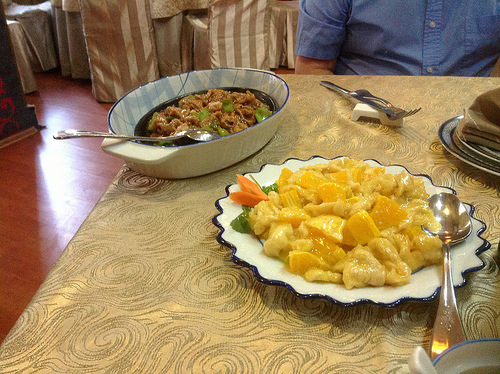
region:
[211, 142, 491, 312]
a white dish on a table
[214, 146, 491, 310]
dish with food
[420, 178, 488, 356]
a silver spoon on side a dish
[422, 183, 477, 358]
a tablespoon on a dish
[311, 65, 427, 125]
a fork on a table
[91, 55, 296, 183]
a white bowl on a table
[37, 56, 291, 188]
a spoon in a bowl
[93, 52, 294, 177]
meat in a bowl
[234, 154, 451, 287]
a salad of potato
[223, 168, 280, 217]
a slice of carrot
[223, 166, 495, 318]
the pasta on the plate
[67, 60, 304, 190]
the dish on the table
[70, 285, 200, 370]
the table cloth with swirl pattern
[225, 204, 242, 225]
garnish on the pasta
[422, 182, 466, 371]
the metal spoon in the pasta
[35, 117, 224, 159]
the giant spoon in the dish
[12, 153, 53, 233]
the floor is hardwood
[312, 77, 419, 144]
the knife and fork on the table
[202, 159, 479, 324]
the plate has ridged edge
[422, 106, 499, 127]
the stack of napkins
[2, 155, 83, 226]
a dark teak wood floor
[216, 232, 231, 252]
dark blue trim on plate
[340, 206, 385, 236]
juicy orange chunk of mango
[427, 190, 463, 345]
a large silver spoon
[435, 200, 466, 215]
light reflecting on the spoon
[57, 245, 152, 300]
silver swirls in the table cloth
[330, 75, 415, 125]
utensils propped on white spoon rest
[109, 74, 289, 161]
a dish of delicious beef stew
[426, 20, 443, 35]
a white button on a blue shirt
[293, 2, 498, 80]
a person sitting at the table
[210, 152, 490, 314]
Culinary preseneted macaroni and cheese on the table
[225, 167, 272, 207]
Slice of carrots next to the macaroni and cheese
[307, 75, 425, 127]
Silver fork and knife on the table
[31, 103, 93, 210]
Reflection of the light on the floor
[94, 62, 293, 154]
Beef stew on a bowl next to the macaroni and cheese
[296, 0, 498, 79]
Person wearing blue shirt sitting next to the table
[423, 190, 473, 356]
Silver spoon next to the macaroni and cheese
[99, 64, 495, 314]
Food on top of the table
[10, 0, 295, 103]
Furniture covered in cloth in the background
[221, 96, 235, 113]
Green pepperoni bells in the stew